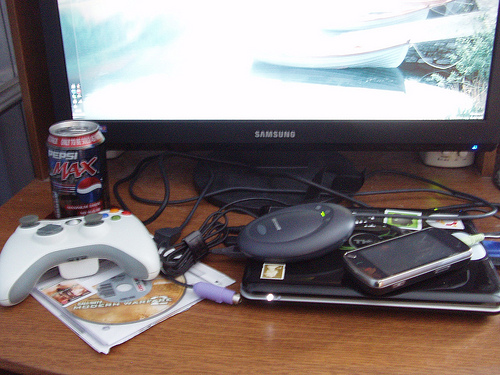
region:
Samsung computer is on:
[36, 0, 496, 152]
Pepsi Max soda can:
[45, 115, 105, 220]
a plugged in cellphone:
[345, 222, 495, 292]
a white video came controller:
[0, 210, 170, 305]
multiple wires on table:
[116, 150, 487, 295]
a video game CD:
[35, 251, 195, 331]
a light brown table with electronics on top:
[0, 111, 497, 368]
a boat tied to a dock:
[247, 31, 477, 66]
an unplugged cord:
[170, 275, 246, 310]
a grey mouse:
[236, 199, 357, 265]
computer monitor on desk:
[27, 14, 487, 220]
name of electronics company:
[243, 120, 303, 145]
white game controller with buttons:
[0, 203, 162, 305]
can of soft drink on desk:
[47, 117, 112, 218]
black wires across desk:
[133, 175, 468, 217]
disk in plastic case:
[65, 272, 192, 337]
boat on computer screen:
[310, 35, 420, 80]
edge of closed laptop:
[240, 277, 497, 315]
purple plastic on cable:
[192, 280, 237, 305]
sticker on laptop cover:
[257, 257, 295, 288]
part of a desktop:
[349, 320, 401, 355]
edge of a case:
[81, 328, 135, 359]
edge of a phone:
[338, 256, 378, 306]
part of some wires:
[356, 180, 410, 228]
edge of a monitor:
[248, 107, 301, 162]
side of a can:
[65, 160, 100, 196]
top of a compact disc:
[103, 283, 134, 312]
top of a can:
[60, 124, 85, 146]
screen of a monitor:
[308, 38, 365, 88]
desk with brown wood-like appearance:
[2, 147, 497, 372]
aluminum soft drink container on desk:
[41, 111, 168, 231]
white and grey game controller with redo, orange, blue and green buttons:
[2, 205, 157, 310]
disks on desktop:
[40, 242, 225, 352]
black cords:
[111, 141, 261, 269]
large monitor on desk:
[22, 0, 493, 205]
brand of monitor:
[245, 120, 302, 143]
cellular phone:
[340, 212, 475, 288]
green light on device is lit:
[246, 200, 351, 250]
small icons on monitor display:
[63, 75, 89, 122]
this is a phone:
[348, 225, 463, 297]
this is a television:
[112, 11, 467, 139]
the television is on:
[165, 25, 345, 107]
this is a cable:
[171, 233, 201, 255]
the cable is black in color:
[177, 257, 183, 263]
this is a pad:
[3, 205, 149, 287]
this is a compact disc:
[73, 282, 164, 320]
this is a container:
[48, 128, 98, 205]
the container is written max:
[46, 157, 101, 178]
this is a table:
[241, 327, 341, 371]